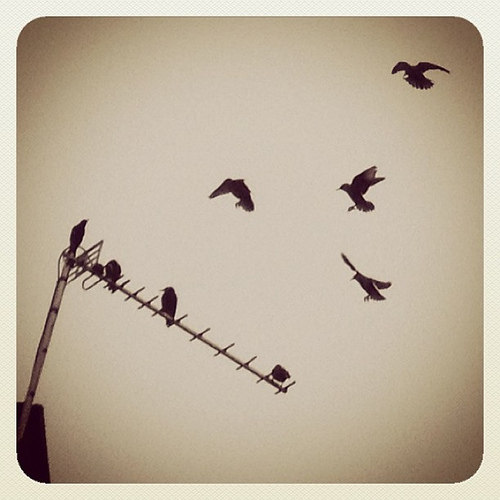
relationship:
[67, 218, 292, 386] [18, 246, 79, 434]
birds are sitting on pole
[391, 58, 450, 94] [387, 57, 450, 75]
bird has its wings spread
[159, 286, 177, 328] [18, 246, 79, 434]
birds perched on pole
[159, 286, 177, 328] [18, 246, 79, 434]
birds sitting at end of pole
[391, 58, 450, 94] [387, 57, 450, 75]
bird with wings in air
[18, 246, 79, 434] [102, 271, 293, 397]
pole with lines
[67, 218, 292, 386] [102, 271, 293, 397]
birds are sitting on antenna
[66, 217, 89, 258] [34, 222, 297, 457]
blackbird sitting on antenna post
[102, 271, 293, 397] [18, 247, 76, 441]
atenna attached to pole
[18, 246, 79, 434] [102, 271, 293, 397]
bar attached to antenna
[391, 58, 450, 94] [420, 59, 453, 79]
bird has a left wing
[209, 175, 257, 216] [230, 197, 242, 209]
bird has claws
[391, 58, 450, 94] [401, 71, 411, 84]
bird has a beak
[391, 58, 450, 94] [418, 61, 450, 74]
bird has left wing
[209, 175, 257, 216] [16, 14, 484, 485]
bird in sky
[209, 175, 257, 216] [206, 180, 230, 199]
bird has wings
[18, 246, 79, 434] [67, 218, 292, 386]
pole under birds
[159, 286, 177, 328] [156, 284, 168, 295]
birds has a beak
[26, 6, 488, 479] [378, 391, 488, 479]
photo has dark part